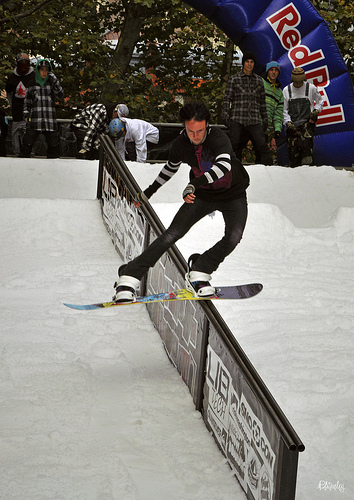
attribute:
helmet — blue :
[108, 118, 125, 140]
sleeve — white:
[313, 87, 325, 112]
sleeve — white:
[280, 85, 291, 124]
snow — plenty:
[2, 158, 350, 498]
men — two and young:
[230, 55, 317, 165]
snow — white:
[1, 158, 350, 339]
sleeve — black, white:
[178, 148, 235, 199]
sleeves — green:
[274, 88, 284, 130]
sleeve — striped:
[182, 147, 230, 194]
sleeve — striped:
[134, 145, 183, 204]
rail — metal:
[204, 298, 303, 451]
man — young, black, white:
[25, 59, 65, 157]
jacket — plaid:
[20, 70, 65, 133]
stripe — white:
[204, 169, 213, 184]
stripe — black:
[208, 168, 218, 181]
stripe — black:
[209, 163, 224, 176]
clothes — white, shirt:
[114, 117, 158, 162]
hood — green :
[32, 56, 54, 79]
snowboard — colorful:
[59, 278, 266, 313]